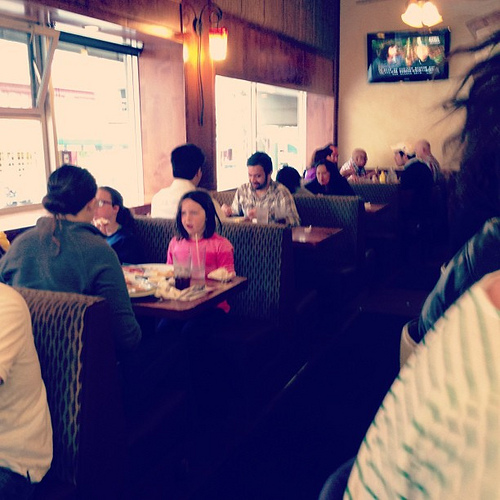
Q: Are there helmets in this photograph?
A: No, there are no helmets.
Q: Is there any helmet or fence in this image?
A: No, there are no helmets or fences.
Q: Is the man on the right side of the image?
A: Yes, the man is on the right of the image.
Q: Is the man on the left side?
A: No, the man is on the right of the image.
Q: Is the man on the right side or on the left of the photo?
A: The man is on the right of the image.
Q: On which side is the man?
A: The man is on the right of the image.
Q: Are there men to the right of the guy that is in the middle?
A: Yes, there is a man to the right of the guy.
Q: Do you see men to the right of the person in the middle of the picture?
A: Yes, there is a man to the right of the guy.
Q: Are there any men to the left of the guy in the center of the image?
A: No, the man is to the right of the guy.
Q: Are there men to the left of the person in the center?
A: No, the man is to the right of the guy.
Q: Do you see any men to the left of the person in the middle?
A: No, the man is to the right of the guy.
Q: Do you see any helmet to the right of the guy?
A: No, there is a man to the right of the guy.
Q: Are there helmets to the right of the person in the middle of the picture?
A: No, there is a man to the right of the guy.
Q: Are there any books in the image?
A: No, there are no books.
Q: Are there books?
A: No, there are no books.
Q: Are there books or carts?
A: No, there are no books or carts.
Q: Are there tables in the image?
A: Yes, there is a table.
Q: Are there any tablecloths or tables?
A: Yes, there is a table.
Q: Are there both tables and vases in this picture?
A: No, there is a table but no vases.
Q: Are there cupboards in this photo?
A: No, there are no cupboards.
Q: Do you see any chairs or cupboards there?
A: No, there are no cupboards or chairs.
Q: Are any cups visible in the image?
A: Yes, there is a cup.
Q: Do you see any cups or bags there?
A: Yes, there is a cup.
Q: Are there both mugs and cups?
A: No, there is a cup but no mugs.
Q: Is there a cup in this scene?
A: Yes, there is a cup.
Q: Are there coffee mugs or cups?
A: Yes, there is a cup.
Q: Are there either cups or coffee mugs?
A: Yes, there is a cup.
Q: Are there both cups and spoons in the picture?
A: No, there is a cup but no spoons.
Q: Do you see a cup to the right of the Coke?
A: Yes, there is a cup to the right of the Coke.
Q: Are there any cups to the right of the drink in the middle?
A: Yes, there is a cup to the right of the Coke.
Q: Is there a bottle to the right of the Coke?
A: No, there is a cup to the right of the Coke.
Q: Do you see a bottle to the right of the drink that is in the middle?
A: No, there is a cup to the right of the Coke.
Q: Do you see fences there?
A: No, there are no fences.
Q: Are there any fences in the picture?
A: No, there are no fences.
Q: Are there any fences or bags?
A: No, there are no fences or bags.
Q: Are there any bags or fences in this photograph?
A: No, there are no fences or bags.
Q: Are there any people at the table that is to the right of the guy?
A: Yes, there are people at the table.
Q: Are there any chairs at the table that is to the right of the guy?
A: No, there are people at the table.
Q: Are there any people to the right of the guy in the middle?
A: Yes, there are people to the right of the guy.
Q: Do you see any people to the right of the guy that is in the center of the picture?
A: Yes, there are people to the right of the guy.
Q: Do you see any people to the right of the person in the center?
A: Yes, there are people to the right of the guy.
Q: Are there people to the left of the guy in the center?
A: No, the people are to the right of the guy.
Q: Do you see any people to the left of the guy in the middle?
A: No, the people are to the right of the guy.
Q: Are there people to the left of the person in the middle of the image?
A: No, the people are to the right of the guy.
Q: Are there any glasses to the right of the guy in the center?
A: No, there are people to the right of the guy.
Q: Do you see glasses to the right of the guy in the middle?
A: No, there are people to the right of the guy.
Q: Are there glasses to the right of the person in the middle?
A: No, there are people to the right of the guy.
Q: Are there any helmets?
A: No, there are no helmets.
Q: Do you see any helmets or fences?
A: No, there are no helmets or fences.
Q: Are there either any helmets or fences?
A: No, there are no helmets or fences.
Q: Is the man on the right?
A: Yes, the man is on the right of the image.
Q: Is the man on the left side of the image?
A: No, the man is on the right of the image.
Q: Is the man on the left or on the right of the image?
A: The man is on the right of the image.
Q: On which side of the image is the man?
A: The man is on the right of the image.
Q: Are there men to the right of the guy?
A: Yes, there is a man to the right of the guy.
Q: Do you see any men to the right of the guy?
A: Yes, there is a man to the right of the guy.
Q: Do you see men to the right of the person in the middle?
A: Yes, there is a man to the right of the guy.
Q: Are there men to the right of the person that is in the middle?
A: Yes, there is a man to the right of the guy.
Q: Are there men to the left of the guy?
A: No, the man is to the right of the guy.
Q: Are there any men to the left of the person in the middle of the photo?
A: No, the man is to the right of the guy.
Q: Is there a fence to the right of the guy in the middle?
A: No, there is a man to the right of the guy.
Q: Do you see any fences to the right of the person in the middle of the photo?
A: No, there is a man to the right of the guy.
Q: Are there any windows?
A: Yes, there is a window.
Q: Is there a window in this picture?
A: Yes, there is a window.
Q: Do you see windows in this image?
A: Yes, there is a window.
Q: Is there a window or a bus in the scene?
A: Yes, there is a window.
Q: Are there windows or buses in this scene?
A: Yes, there is a window.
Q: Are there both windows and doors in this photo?
A: No, there is a window but no doors.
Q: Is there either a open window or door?
A: Yes, there is an open window.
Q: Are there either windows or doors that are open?
A: Yes, the window is open.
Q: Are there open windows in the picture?
A: Yes, there is an open window.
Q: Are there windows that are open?
A: Yes, there is a window that is open.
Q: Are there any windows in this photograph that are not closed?
A: Yes, there is a open window.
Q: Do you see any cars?
A: No, there are no cars.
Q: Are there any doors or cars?
A: No, there are no cars or doors.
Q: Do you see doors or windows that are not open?
A: No, there is a window but it is open.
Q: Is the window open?
A: Yes, the window is open.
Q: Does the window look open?
A: Yes, the window is open.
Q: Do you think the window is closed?
A: No, the window is open.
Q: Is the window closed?
A: No, the window is open.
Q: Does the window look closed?
A: No, the window is open.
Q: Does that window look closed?
A: No, the window is open.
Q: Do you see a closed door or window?
A: No, there is a window but it is open.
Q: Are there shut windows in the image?
A: No, there is a window but it is open.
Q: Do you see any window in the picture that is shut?
A: No, there is a window but it is open.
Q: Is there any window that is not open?
A: No, there is a window but it is open.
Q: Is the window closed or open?
A: The window is open.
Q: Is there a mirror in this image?
A: No, there are no mirrors.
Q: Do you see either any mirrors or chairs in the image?
A: No, there are no mirrors or chairs.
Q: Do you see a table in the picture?
A: Yes, there is a table.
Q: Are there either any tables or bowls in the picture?
A: Yes, there is a table.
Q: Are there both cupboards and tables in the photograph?
A: No, there is a table but no cupboards.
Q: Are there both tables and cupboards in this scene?
A: No, there is a table but no cupboards.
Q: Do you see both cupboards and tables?
A: No, there is a table but no cupboards.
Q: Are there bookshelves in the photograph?
A: No, there are no bookshelves.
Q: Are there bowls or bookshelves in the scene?
A: No, there are no bookshelves or bowls.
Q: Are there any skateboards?
A: No, there are no skateboards.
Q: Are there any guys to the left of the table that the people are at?
A: Yes, there is a guy to the left of the table.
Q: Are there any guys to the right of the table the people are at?
A: No, the guy is to the left of the table.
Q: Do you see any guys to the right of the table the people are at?
A: No, the guy is to the left of the table.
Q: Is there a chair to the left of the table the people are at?
A: No, there is a guy to the left of the table.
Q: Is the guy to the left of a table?
A: Yes, the guy is to the left of a table.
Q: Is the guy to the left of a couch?
A: No, the guy is to the left of a table.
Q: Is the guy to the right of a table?
A: No, the guy is to the left of a table.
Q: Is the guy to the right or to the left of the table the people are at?
A: The guy is to the left of the table.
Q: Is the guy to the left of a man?
A: Yes, the guy is to the left of a man.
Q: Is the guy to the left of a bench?
A: No, the guy is to the left of a man.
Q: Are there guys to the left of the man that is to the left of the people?
A: Yes, there is a guy to the left of the man.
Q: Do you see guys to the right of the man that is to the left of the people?
A: No, the guy is to the left of the man.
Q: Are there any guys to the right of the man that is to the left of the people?
A: No, the guy is to the left of the man.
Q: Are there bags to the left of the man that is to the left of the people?
A: No, there is a guy to the left of the man.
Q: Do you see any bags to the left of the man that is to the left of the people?
A: No, there is a guy to the left of the man.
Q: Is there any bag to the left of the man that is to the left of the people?
A: No, there is a guy to the left of the man.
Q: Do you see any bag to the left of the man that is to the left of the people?
A: No, there is a guy to the left of the man.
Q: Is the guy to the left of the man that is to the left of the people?
A: Yes, the guy is to the left of the man.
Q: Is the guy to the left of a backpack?
A: No, the guy is to the left of the man.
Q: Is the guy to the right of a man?
A: No, the guy is to the left of a man.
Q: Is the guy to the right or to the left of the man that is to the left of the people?
A: The guy is to the left of the man.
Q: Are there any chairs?
A: No, there are no chairs.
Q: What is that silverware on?
A: The silverware is on the table.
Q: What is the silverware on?
A: The silverware is on the table.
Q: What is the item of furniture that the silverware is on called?
A: The piece of furniture is a table.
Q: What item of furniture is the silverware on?
A: The silverware is on the table.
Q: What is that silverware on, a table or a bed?
A: The silverware is on a table.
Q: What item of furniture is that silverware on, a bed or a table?
A: The silverware is on a table.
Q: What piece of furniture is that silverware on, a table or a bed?
A: The silverware is on a table.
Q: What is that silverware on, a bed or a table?
A: The silverware is on a table.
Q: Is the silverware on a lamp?
A: No, the silverware is on the table.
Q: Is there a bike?
A: No, there are no bikes.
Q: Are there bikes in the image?
A: No, there are no bikes.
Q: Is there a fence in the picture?
A: No, there are no fences.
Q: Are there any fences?
A: No, there are no fences.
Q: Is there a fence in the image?
A: No, there are no fences.